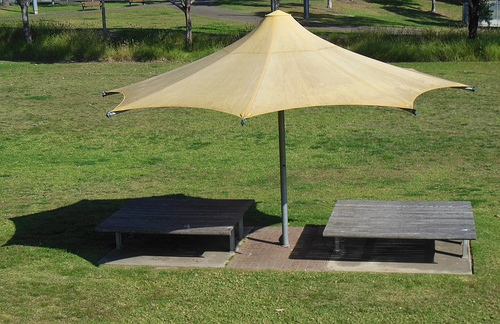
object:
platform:
[321, 199, 478, 264]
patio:
[92, 9, 477, 276]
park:
[0, 0, 500, 324]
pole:
[276, 109, 289, 247]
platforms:
[91, 198, 254, 251]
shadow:
[0, 193, 296, 268]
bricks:
[291, 246, 334, 263]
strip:
[87, 227, 238, 236]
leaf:
[274, 289, 369, 319]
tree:
[97, 0, 109, 45]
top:
[240, 8, 316, 43]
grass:
[333, 134, 424, 183]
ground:
[222, 246, 469, 271]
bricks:
[234, 246, 262, 267]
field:
[0, 0, 500, 182]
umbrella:
[101, 8, 471, 126]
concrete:
[240, 249, 289, 263]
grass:
[0, 20, 225, 64]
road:
[173, 0, 262, 22]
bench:
[79, 0, 105, 11]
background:
[0, 0, 500, 65]